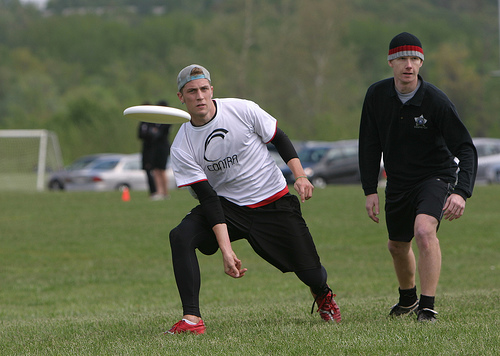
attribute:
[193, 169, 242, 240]
sleeve — black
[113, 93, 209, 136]
frisbee — white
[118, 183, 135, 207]
cone — orange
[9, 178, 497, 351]
field — grassy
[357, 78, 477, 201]
shirt — long sleeve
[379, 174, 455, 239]
shorts — black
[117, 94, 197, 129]
disk — FRISBEE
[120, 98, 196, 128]
disk — FRISBEE, WHITE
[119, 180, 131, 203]
cone — ORANGE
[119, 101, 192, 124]
frisbee — WHITE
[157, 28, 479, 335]
players — FRISBEE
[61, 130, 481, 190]
lot — PARKING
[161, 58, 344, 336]
player — FRISBEE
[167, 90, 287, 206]
t-shirt — WHITE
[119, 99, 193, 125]
frisbee — ULTIMATE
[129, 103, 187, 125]
frisbee — white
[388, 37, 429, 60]
cap — ski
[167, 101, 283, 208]
tee shirt — white, black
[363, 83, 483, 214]
shirt — black, long sleeved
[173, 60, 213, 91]
hat — grey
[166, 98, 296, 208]
shirt — white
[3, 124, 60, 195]
net — soccer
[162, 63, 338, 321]
person — couple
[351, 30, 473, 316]
person — couple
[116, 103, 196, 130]
frisbee — white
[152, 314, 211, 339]
shoe — red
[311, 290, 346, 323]
shoe — red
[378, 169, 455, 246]
pants — black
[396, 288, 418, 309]
sock — black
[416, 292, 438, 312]
sock — black